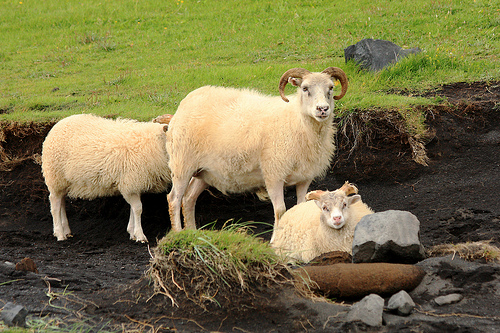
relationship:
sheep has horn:
[174, 59, 351, 188] [270, 68, 302, 102]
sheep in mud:
[27, 105, 166, 250] [94, 248, 112, 266]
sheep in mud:
[174, 59, 351, 188] [94, 248, 112, 266]